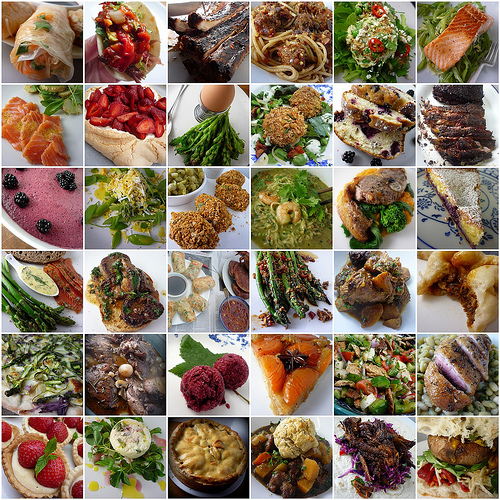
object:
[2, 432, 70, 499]
tart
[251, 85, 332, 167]
vegetable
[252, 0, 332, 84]
spaghetti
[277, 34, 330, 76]
meatballs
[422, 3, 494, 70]
fish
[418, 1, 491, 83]
noodles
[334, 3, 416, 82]
slaw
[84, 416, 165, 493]
vegetable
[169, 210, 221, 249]
breaded objects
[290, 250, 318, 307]
asparagus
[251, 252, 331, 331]
white plate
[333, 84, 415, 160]
bread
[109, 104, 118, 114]
red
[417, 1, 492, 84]
greens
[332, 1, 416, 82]
greens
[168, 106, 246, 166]
greens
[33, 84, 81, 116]
greens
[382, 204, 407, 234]
greens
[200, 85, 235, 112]
egg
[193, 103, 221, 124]
egg cup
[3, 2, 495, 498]
types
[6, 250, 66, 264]
bread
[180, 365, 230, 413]
red berries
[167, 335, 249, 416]
plate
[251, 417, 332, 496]
stew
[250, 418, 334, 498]
bowl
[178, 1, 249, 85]
meat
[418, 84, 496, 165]
meat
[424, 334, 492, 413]
meat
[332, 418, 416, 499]
meat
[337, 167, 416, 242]
meat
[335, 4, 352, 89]
vegetable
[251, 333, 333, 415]
orange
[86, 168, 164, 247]
vegetable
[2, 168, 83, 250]
dessert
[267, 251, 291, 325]
asparagus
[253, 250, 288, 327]
asparagus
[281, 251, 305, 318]
asparagus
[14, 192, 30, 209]
raspberry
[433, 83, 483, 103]
piece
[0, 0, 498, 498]
picture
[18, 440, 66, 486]
strawberry